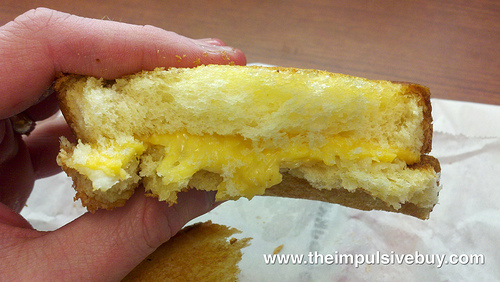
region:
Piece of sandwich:
[47, 40, 450, 230]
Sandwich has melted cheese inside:
[47, 55, 454, 240]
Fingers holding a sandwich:
[3, 3, 248, 276]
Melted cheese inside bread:
[95, 131, 412, 167]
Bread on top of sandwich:
[52, 57, 443, 146]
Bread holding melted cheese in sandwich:
[71, 164, 454, 221]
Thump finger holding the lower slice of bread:
[25, 168, 252, 280]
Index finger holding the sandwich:
[0, 5, 247, 93]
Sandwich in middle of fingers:
[43, 59, 455, 226]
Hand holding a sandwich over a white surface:
[0, 16, 498, 276]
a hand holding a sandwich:
[3, 3, 453, 280]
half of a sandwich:
[44, 42, 451, 227]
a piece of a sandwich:
[104, 217, 259, 279]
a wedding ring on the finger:
[2, 95, 47, 151]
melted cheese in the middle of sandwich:
[67, 107, 424, 205]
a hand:
[0, 8, 249, 279]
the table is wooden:
[1, 0, 498, 110]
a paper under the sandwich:
[12, 52, 496, 274]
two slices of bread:
[47, 45, 447, 225]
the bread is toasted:
[48, 47, 454, 227]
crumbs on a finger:
[135, 31, 231, 61]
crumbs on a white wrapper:
[269, 231, 319, 261]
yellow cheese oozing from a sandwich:
[182, 131, 237, 166]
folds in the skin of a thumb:
[143, 203, 173, 245]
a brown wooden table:
[348, 23, 420, 63]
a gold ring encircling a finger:
[14, 114, 49, 139]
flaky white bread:
[203, 76, 323, 124]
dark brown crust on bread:
[419, 89, 442, 152]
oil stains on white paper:
[262, 202, 321, 242]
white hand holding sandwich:
[6, 12, 443, 271]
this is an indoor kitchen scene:
[8, 12, 496, 279]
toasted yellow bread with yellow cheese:
[45, 52, 448, 267]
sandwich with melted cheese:
[46, 64, 439, 271]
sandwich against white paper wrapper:
[0, 21, 499, 276]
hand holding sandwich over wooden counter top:
[5, 1, 497, 273]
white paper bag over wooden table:
[6, 9, 498, 277]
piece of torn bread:
[126, 217, 256, 279]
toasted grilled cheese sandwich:
[39, 56, 443, 228]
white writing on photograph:
[258, 242, 485, 266]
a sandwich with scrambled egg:
[57, 60, 438, 220]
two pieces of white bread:
[60, 65, 440, 221]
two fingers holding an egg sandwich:
[57, 10, 258, 243]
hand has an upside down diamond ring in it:
[5, 103, 41, 168]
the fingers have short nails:
[125, 15, 246, 77]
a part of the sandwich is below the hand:
[117, 220, 253, 280]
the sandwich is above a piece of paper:
[15, 61, 496, 276]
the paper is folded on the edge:
[416, 90, 497, 161]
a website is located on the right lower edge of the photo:
[260, 241, 488, 271]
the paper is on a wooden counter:
[8, 0, 499, 137]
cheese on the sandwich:
[98, 26, 383, 280]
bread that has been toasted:
[247, 78, 354, 220]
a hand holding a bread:
[40, 42, 302, 269]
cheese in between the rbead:
[137, 75, 289, 173]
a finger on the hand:
[185, 33, 237, 71]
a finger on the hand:
[70, 205, 278, 280]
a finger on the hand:
[41, 123, 226, 275]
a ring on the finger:
[2, 99, 42, 153]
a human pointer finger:
[8, 5, 253, 103]